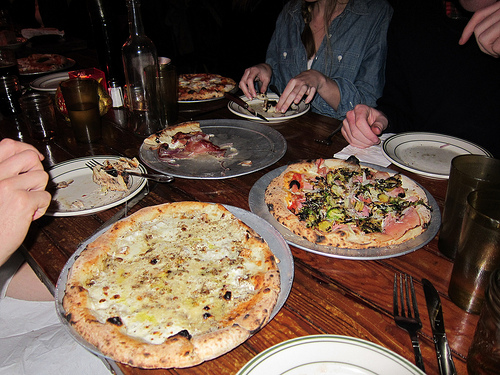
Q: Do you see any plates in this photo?
A: Yes, there is a plate.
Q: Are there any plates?
A: Yes, there is a plate.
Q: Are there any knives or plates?
A: Yes, there is a plate.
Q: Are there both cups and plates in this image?
A: Yes, there are both a plate and a cup.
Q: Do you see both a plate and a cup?
A: Yes, there are both a plate and a cup.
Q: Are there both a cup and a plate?
A: Yes, there are both a plate and a cup.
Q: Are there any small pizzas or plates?
A: Yes, there is a small plate.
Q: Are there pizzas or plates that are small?
A: Yes, the plate is small.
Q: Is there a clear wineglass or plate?
A: Yes, there is a clear plate.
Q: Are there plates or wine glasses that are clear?
A: Yes, the plate is clear.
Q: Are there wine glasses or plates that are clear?
A: Yes, the plate is clear.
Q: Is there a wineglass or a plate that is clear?
A: Yes, the plate is clear.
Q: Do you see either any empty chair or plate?
A: Yes, there is an empty plate.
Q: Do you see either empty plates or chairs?
A: Yes, there is an empty plate.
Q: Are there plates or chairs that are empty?
A: Yes, the plate is empty.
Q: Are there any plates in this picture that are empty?
A: Yes, there is an empty plate.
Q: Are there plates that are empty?
A: Yes, there is a plate that is empty.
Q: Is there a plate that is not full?
A: Yes, there is a empty plate.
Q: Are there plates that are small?
A: Yes, there is a small plate.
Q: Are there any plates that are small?
A: Yes, there is a plate that is small.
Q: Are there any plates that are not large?
A: Yes, there is a small plate.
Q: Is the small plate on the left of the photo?
A: Yes, the plate is on the left of the image.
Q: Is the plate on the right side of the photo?
A: No, the plate is on the left of the image.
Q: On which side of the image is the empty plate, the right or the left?
A: The plate is on the left of the image.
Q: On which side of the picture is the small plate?
A: The plate is on the left of the image.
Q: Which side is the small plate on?
A: The plate is on the left of the image.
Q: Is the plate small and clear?
A: Yes, the plate is small and clear.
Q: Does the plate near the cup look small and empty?
A: Yes, the plate is small and empty.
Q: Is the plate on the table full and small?
A: No, the plate is small but empty.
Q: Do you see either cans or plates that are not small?
A: No, there is a plate but it is small.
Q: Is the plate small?
A: Yes, the plate is small.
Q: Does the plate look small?
A: Yes, the plate is small.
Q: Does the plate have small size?
A: Yes, the plate is small.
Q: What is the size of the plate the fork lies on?
A: The plate is small.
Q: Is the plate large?
A: No, the plate is small.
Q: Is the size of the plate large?
A: No, the plate is small.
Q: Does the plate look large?
A: No, the plate is small.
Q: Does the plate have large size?
A: No, the plate is small.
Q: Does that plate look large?
A: No, the plate is small.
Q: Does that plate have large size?
A: No, the plate is small.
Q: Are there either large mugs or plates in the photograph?
A: No, there is a plate but it is small.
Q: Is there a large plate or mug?
A: No, there is a plate but it is small.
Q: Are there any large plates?
A: No, there is a plate but it is small.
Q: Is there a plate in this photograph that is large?
A: No, there is a plate but it is small.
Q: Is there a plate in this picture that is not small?
A: No, there is a plate but it is small.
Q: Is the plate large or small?
A: The plate is small.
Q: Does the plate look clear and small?
A: Yes, the plate is clear and small.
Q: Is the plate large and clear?
A: No, the plate is clear but small.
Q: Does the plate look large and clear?
A: No, the plate is clear but small.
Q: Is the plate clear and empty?
A: Yes, the plate is clear and empty.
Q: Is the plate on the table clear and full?
A: No, the plate is clear but empty.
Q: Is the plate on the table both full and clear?
A: No, the plate is clear but empty.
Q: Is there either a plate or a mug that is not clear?
A: No, there is a plate but it is clear.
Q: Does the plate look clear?
A: Yes, the plate is clear.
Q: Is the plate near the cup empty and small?
A: Yes, the plate is empty and small.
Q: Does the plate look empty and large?
A: No, the plate is empty but small.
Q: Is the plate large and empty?
A: No, the plate is empty but small.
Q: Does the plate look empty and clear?
A: Yes, the plate is empty and clear.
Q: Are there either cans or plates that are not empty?
A: No, there is a plate but it is empty.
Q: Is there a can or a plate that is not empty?
A: No, there is a plate but it is empty.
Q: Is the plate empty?
A: Yes, the plate is empty.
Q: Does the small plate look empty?
A: Yes, the plate is empty.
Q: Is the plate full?
A: No, the plate is empty.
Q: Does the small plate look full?
A: No, the plate is empty.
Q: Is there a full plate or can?
A: No, there is a plate but it is empty.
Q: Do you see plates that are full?
A: No, there is a plate but it is empty.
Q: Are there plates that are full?
A: No, there is a plate but it is empty.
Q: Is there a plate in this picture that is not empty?
A: No, there is a plate but it is empty.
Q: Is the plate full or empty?
A: The plate is empty.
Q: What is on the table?
A: The plate is on the table.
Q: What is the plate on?
A: The plate is on the table.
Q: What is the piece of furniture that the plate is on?
A: The piece of furniture is a table.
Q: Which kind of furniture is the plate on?
A: The plate is on the table.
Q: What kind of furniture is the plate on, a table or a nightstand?
A: The plate is on a table.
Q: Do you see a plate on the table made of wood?
A: Yes, there is a plate on the table.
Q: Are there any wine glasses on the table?
A: No, there is a plate on the table.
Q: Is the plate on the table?
A: Yes, the plate is on the table.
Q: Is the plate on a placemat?
A: No, the plate is on the table.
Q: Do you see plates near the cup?
A: Yes, there is a plate near the cup.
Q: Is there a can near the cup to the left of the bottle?
A: No, there is a plate near the cup.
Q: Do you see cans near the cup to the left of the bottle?
A: No, there is a plate near the cup.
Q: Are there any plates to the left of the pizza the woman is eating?
A: Yes, there is a plate to the left of the pizza.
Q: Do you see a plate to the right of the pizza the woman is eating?
A: No, the plate is to the left of the pizza.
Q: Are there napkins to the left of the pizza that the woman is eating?
A: No, there is a plate to the left of the pizza.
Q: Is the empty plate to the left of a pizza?
A: Yes, the plate is to the left of a pizza.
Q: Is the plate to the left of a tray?
A: No, the plate is to the left of a pizza.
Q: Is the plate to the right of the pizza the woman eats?
A: No, the plate is to the left of the pizza.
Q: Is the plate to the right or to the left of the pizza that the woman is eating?
A: The plate is to the left of the pizza.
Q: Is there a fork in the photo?
A: Yes, there is a fork.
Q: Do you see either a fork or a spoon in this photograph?
A: Yes, there is a fork.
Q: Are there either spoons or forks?
A: Yes, there is a fork.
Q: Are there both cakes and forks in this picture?
A: No, there is a fork but no cakes.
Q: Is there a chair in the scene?
A: No, there are no chairs.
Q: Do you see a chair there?
A: No, there are no chairs.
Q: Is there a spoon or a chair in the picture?
A: No, there are no chairs or spoons.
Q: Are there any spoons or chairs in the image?
A: No, there are no chairs or spoons.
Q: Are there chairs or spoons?
A: No, there are no chairs or spoons.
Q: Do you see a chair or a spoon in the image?
A: No, there are no chairs or spoons.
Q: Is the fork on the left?
A: Yes, the fork is on the left of the image.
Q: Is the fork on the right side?
A: No, the fork is on the left of the image.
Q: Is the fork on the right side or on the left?
A: The fork is on the left of the image.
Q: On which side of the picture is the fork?
A: The fork is on the left of the image.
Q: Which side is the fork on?
A: The fork is on the left of the image.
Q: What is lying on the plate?
A: The fork is lying on the plate.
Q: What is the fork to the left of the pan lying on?
A: The fork is lying on the plate.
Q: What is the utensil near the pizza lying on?
A: The fork is lying on the plate.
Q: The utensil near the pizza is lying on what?
A: The fork is lying on the plate.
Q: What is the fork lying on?
A: The fork is lying on the plate.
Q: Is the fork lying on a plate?
A: Yes, the fork is lying on a plate.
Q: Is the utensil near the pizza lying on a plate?
A: Yes, the fork is lying on a plate.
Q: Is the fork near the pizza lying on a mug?
A: No, the fork is lying on a plate.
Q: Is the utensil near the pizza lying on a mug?
A: No, the fork is lying on a plate.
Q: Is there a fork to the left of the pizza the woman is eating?
A: Yes, there is a fork to the left of the pizza.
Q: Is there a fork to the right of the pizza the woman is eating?
A: No, the fork is to the left of the pizza.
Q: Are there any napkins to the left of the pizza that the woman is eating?
A: No, there is a fork to the left of the pizza.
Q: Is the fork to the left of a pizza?
A: Yes, the fork is to the left of a pizza.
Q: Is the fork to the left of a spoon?
A: No, the fork is to the left of a pizza.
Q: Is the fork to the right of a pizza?
A: No, the fork is to the left of a pizza.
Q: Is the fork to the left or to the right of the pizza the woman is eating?
A: The fork is to the left of the pizza.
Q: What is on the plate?
A: The fork is on the plate.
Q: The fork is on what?
A: The fork is on the plate.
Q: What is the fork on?
A: The fork is on the plate.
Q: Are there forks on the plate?
A: Yes, there is a fork on the plate.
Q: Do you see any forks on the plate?
A: Yes, there is a fork on the plate.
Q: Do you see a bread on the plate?
A: No, there is a fork on the plate.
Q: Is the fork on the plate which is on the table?
A: Yes, the fork is on the plate.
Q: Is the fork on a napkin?
A: No, the fork is on the plate.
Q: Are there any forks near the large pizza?
A: Yes, there is a fork near the pizza.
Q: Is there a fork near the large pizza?
A: Yes, there is a fork near the pizza.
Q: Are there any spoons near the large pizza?
A: No, there is a fork near the pizza.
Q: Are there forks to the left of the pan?
A: Yes, there is a fork to the left of the pan.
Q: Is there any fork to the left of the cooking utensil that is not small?
A: Yes, there is a fork to the left of the pan.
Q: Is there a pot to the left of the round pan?
A: No, there is a fork to the left of the pan.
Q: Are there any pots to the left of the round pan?
A: No, there is a fork to the left of the pan.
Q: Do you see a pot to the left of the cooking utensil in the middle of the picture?
A: No, there is a fork to the left of the pan.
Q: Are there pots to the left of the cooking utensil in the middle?
A: No, there is a fork to the left of the pan.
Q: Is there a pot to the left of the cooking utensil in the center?
A: No, there is a fork to the left of the pan.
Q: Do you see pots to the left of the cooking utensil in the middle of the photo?
A: No, there is a fork to the left of the pan.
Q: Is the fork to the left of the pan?
A: Yes, the fork is to the left of the pan.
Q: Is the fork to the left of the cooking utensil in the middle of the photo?
A: Yes, the fork is to the left of the pan.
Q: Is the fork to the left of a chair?
A: No, the fork is to the left of the pan.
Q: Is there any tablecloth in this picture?
A: No, there are no tablecloths.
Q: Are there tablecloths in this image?
A: No, there are no tablecloths.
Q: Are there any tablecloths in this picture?
A: No, there are no tablecloths.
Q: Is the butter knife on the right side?
A: Yes, the butter knife is on the right of the image.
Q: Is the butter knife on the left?
A: No, the butter knife is on the right of the image.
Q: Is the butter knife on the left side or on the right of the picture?
A: The butter knife is on the right of the image.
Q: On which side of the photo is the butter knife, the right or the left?
A: The butter knife is on the right of the image.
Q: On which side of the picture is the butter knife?
A: The butter knife is on the right of the image.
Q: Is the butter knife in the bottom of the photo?
A: Yes, the butter knife is in the bottom of the image.